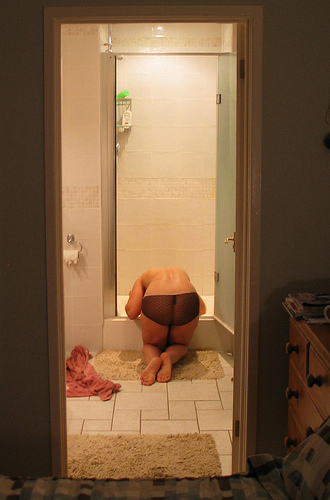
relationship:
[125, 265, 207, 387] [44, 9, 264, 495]
lady viewed through door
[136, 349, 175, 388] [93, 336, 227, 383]
feet on rug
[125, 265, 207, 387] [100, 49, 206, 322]
lady kneeling into shower stall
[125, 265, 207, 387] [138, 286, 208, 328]
lady in panties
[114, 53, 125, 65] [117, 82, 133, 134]
shower with products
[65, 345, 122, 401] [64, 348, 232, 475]
towel lying on bathroom floor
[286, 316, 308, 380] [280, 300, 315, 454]
drawer built into dresser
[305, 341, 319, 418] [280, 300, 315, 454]
drawer built into dresser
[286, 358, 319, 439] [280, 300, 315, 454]
drawer built into dresser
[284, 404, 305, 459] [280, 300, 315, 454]
drawer built into dresser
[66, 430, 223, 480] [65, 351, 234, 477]
rug lying on floor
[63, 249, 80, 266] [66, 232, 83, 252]
tissue hanging from dispenser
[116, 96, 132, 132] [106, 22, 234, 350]
rack hanging in shower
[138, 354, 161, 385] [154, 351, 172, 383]
foot placed next to foot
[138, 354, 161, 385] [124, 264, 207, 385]
foot belonging to lady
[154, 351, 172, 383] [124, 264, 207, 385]
foot belonging to lady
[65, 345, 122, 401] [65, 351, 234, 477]
towel lying on floor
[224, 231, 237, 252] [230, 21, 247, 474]
handle mounted on door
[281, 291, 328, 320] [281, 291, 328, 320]
book lying in book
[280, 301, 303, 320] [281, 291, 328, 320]
book lying in book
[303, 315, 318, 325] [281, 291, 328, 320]
book lying in book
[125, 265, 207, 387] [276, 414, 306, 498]
lady sitting near pillow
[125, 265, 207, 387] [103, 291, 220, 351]
lady bent over tub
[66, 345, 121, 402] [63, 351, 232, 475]
garment lying on ground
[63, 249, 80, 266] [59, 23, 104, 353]
tissue hanging from wall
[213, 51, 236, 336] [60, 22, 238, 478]
shower door hanging in bathroom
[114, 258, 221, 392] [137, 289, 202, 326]
lady in panties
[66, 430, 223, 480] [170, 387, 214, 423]
rug on floor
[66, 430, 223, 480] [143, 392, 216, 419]
rug on floor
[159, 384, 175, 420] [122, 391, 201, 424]
lines on floor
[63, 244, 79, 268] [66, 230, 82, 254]
paper on roll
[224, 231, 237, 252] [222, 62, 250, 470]
handle on door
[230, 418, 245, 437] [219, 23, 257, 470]
hinge on door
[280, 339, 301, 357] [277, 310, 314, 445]
knob on dresser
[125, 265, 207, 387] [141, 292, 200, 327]
lady wearing panties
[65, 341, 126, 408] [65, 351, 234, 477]
towel on floor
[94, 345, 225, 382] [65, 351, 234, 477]
rug on floor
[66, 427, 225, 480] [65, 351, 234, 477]
rug on floor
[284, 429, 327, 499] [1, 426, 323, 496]
pillow on bed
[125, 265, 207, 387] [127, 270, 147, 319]
lady has arm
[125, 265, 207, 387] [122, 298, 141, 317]
lady has elbow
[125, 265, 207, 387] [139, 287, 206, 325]
lady wearing panties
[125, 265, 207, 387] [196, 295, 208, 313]
lady has elbow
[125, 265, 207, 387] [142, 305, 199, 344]
lady has thighs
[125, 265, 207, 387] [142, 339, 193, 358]
lady has calves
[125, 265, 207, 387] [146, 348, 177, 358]
lady has heels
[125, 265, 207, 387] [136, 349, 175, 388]
lady has feet